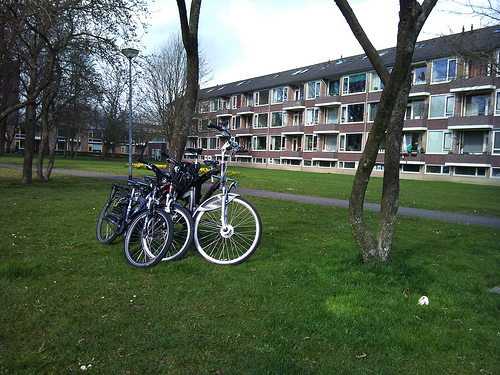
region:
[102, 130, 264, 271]
Bikes resting against a tree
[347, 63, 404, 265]
Trunks of a thin tree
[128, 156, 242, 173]
Yellow flowers in a field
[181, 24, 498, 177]
A large apartment building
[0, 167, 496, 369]
Green grass of a field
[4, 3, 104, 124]
Brown tree branches lacking leaves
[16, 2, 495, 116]
A cloudy, blue sky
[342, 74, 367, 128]
Windows on an apartment building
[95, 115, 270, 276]
bicycles leaning on tree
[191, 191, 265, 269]
front tire on bicycle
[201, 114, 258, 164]
black handlebar on bicycle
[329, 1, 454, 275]
three tree trunks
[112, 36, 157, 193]
street lamp in grass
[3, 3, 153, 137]
bare tree branches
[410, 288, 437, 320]
leaf in grass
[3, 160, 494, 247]
grey cement walkway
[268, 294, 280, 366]
There is a patch of green grass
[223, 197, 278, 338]
There is a black tire here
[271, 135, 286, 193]
There are windows here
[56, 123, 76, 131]
There is a tree that is in the distance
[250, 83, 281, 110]
window of a building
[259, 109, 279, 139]
window of a building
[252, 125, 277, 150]
window of a building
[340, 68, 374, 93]
window of a building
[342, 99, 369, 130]
window of a building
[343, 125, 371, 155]
window of a building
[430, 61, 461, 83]
window of a building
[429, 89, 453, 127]
window of a building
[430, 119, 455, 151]
window of a building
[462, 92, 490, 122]
window of a building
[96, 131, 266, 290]
bikes parked in the lawn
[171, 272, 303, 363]
green grass of a lawn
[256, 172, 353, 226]
pathway besides the grass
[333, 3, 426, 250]
trunk of a tree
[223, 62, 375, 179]
building in the distance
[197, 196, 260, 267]
tire of a bicycle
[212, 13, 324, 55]
cloudy sky in the distance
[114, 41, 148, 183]
light on a pole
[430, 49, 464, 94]
window on a building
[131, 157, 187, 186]
handle bars on a bike